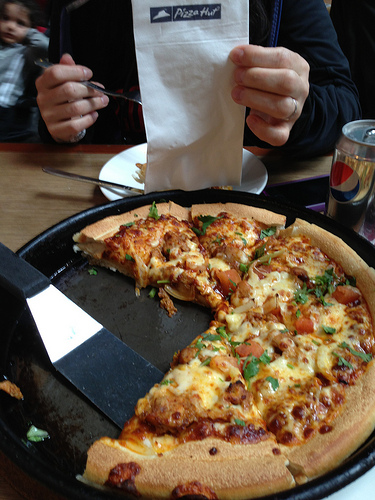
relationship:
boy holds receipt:
[35, 0, 362, 159] [129, 5, 253, 188]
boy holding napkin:
[35, 0, 362, 159] [129, 0, 247, 194]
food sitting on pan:
[74, 201, 375, 500] [0, 186, 374, 500]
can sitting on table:
[327, 116, 373, 242] [2, 140, 333, 253]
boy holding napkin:
[35, 0, 362, 159] [138, 28, 230, 157]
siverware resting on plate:
[38, 160, 245, 194] [96, 139, 269, 201]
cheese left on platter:
[104, 213, 374, 453] [0, 186, 373, 498]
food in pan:
[98, 190, 363, 289] [0, 186, 374, 500]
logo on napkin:
[151, 9, 168, 20] [124, 7, 258, 204]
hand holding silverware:
[33, 51, 110, 140] [49, 66, 144, 116]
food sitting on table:
[74, 201, 375, 500] [18, 146, 371, 242]